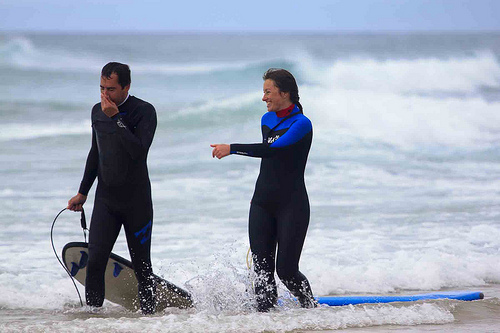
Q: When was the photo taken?
A: Daytime.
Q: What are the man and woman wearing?
A: Bodysuits.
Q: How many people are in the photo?
A: Two.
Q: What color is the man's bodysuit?
A: Black.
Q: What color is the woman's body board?
A: Blue.